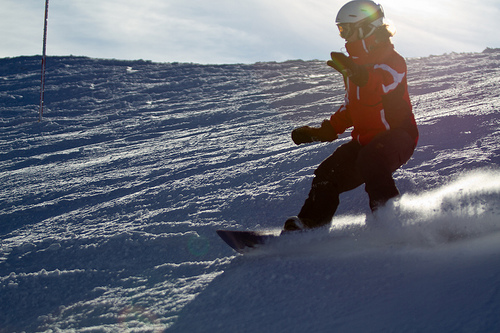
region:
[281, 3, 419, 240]
snowboarder in red uniform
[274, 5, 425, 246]
snowboarder with gray helmet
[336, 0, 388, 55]
gray helmet on snowboarder head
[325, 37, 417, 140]
wine red and white jacket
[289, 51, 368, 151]
wine gloves of snowboarder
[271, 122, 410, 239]
black pants of snowboarder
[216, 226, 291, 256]
part of snowboard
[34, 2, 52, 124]
large gray pole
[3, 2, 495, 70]
light blue and cloudy sky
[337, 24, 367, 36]
big lenses of snowboarder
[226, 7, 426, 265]
a person snow boarding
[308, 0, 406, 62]
a person wearing goggles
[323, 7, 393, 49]
a person wearing a helmet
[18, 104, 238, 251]
ground covered with snow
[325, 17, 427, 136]
a person wearing a red and white jacket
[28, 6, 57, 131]
a pole stuck in the ground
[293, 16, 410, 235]
a person wearing black pants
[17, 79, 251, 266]
tracks in the snow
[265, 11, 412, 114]
a person holding their hand out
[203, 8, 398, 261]
a person on a snow board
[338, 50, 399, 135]
Person wearing a red jacket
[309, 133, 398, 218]
person in black pants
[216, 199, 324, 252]
person on snow board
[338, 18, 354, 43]
person wearing ski googles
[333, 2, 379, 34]
person in white helmet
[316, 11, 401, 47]
person in white helmet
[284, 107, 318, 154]
person wearing gloves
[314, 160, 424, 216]
person in ski pants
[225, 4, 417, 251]
snowboarder on snowy slope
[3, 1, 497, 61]
cloud cover in sky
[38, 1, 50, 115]
metal pole in snow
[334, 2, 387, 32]
helmet on snowboarder's head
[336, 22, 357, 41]
goggles on person's face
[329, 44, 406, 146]
red and white winter jacket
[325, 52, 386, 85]
extended hand in glove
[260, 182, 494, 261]
snow flying into the air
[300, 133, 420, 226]
winter pants on person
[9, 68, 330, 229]
lines in snow surface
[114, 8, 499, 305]
a person snowboarding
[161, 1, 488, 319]
a person that is surfboard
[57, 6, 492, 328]
a person surfboard on snow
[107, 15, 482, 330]
a snowboarder on snow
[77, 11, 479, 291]
a snowboarder going down on a hill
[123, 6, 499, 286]
a person going down snow hill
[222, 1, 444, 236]
a person wearing a jacket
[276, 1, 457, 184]
a person wearing red jacket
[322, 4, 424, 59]
a person wearing helmet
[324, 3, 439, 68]
a person wearing silver helmet